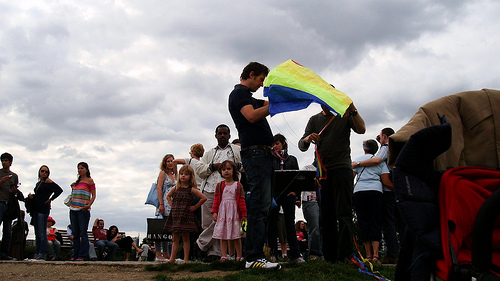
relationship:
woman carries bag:
[152, 148, 182, 258] [148, 176, 165, 204]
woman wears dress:
[152, 148, 182, 258] [158, 170, 180, 211]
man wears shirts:
[375, 126, 395, 150] [353, 143, 393, 193]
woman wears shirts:
[358, 141, 392, 261] [353, 143, 393, 193]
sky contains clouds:
[0, 1, 497, 245] [285, 0, 466, 63]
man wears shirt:
[226, 61, 309, 274] [242, 91, 292, 138]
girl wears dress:
[161, 166, 208, 268] [162, 184, 201, 234]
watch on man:
[355, 160, 359, 168] [353, 127, 393, 172]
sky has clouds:
[0, 1, 497, 245] [285, 0, 466, 63]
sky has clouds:
[0, 1, 497, 245] [50, 31, 162, 108]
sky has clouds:
[0, 1, 497, 245] [1, 111, 138, 156]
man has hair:
[226, 61, 309, 274] [236, 60, 271, 83]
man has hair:
[226, 61, 309, 274] [240, 60, 269, 79]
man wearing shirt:
[221, 59, 310, 274] [223, 85, 280, 145]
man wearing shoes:
[226, 61, 309, 274] [223, 248, 288, 273]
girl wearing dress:
[208, 160, 247, 262] [213, 180, 244, 239]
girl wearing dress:
[159, 166, 207, 265] [164, 185, 198, 235]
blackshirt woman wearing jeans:
[29, 163, 62, 261] [26, 207, 67, 263]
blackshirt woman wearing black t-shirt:
[29, 163, 62, 261] [32, 181, 53, 200]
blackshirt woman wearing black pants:
[29, 163, 62, 261] [30, 213, 52, 251]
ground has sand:
[39, 261, 114, 279] [0, 257, 266, 278]